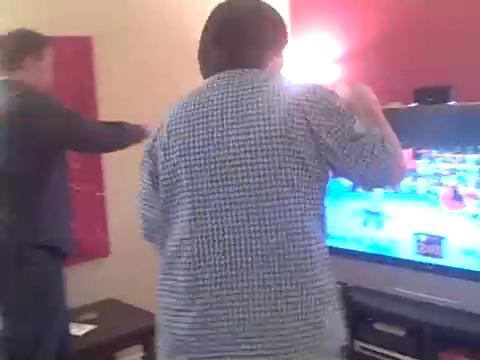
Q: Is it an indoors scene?
A: Yes, it is indoors.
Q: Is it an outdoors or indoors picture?
A: It is indoors.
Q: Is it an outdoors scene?
A: No, it is indoors.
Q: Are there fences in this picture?
A: No, there are no fences.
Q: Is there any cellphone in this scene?
A: No, there are no cell phones.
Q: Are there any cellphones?
A: No, there are no cellphones.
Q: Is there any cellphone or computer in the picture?
A: No, there are no cell phones or computers.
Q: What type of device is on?
A: The device is a screen.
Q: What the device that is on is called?
A: The device is a screen.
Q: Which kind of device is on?
A: The device is a screen.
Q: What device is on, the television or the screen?
A: The screen is on.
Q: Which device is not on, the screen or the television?
A: The television is not on.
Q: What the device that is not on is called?
A: The device is a television.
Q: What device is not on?
A: The device is a television.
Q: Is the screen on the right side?
A: Yes, the screen is on the right of the image.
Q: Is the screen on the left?
A: No, the screen is on the right of the image.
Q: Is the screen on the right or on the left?
A: The screen is on the right of the image.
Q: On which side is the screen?
A: The screen is on the right of the image.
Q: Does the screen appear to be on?
A: Yes, the screen is on.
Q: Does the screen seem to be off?
A: No, the screen is on.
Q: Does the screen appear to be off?
A: No, the screen is on.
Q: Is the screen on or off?
A: The screen is on.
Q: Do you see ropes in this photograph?
A: No, there are no ropes.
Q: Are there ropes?
A: No, there are no ropes.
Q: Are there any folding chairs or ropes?
A: No, there are no ropes or folding chairs.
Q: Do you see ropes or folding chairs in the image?
A: No, there are no ropes or folding chairs.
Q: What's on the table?
A: The paper is on the table.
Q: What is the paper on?
A: The paper is on the table.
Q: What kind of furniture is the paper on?
A: The paper is on the table.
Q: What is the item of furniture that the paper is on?
A: The piece of furniture is a table.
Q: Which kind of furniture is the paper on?
A: The paper is on the table.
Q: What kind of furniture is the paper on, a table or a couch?
A: The paper is on a table.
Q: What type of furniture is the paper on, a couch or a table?
A: The paper is on a table.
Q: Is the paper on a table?
A: Yes, the paper is on a table.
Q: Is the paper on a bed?
A: No, the paper is on a table.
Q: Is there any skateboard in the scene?
A: No, there are no skateboards.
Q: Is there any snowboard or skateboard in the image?
A: No, there are no skateboards or snowboards.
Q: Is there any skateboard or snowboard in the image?
A: No, there are no skateboards or snowboards.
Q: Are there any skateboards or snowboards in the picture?
A: No, there are no skateboards or snowboards.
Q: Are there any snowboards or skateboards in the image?
A: No, there are no skateboards or snowboards.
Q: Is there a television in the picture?
A: Yes, there is a television.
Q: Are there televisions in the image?
A: Yes, there is a television.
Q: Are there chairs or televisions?
A: Yes, there is a television.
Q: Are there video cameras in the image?
A: No, there are no video cameras.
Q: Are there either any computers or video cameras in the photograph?
A: No, there are no video cameras or computers.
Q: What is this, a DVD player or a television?
A: This is a television.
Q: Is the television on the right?
A: Yes, the television is on the right of the image.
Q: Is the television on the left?
A: No, the television is on the right of the image.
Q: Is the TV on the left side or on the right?
A: The TV is on the right of the image.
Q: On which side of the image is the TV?
A: The TV is on the right of the image.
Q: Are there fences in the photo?
A: No, there are no fences.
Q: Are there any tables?
A: Yes, there is a table.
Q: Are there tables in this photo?
A: Yes, there is a table.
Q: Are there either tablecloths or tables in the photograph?
A: Yes, there is a table.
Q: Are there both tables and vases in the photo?
A: No, there is a table but no vases.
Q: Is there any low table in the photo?
A: Yes, there is a low table.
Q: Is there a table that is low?
A: Yes, there is a table that is low.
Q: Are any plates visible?
A: No, there are no plates.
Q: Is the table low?
A: Yes, the table is low.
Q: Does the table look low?
A: Yes, the table is low.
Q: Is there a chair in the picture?
A: No, there are no chairs.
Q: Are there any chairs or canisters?
A: No, there are no chairs or canisters.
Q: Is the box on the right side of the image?
A: Yes, the box is on the right of the image.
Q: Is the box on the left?
A: No, the box is on the right of the image.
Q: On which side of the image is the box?
A: The box is on the right of the image.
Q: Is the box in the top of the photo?
A: No, the box is in the bottom of the image.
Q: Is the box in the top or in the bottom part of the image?
A: The box is in the bottom of the image.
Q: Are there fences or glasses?
A: No, there are no fences or glasses.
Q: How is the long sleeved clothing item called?
A: The clothing item is a shirt.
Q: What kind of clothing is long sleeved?
A: The clothing is a shirt.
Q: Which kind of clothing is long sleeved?
A: The clothing is a shirt.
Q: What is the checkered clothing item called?
A: The clothing item is a shirt.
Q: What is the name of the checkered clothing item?
A: The clothing item is a shirt.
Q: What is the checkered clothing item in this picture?
A: The clothing item is a shirt.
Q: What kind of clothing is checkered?
A: The clothing is a shirt.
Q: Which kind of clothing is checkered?
A: The clothing is a shirt.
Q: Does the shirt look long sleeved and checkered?
A: Yes, the shirt is long sleeved and checkered.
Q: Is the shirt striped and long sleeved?
A: No, the shirt is long sleeved but checkered.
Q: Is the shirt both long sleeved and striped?
A: No, the shirt is long sleeved but checkered.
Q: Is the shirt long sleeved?
A: Yes, the shirt is long sleeved.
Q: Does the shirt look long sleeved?
A: Yes, the shirt is long sleeved.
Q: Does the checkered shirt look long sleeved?
A: Yes, the shirt is long sleeved.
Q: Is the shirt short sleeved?
A: No, the shirt is long sleeved.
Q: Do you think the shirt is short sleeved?
A: No, the shirt is long sleeved.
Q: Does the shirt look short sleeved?
A: No, the shirt is long sleeved.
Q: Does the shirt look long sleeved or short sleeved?
A: The shirt is long sleeved.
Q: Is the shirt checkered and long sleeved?
A: Yes, the shirt is checkered and long sleeved.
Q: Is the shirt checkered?
A: Yes, the shirt is checkered.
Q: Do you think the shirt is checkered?
A: Yes, the shirt is checkered.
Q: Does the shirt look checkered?
A: Yes, the shirt is checkered.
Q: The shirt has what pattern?
A: The shirt is checkered.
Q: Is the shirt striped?
A: No, the shirt is checkered.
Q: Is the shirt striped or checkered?
A: The shirt is checkered.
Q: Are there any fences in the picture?
A: No, there are no fences.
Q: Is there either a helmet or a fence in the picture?
A: No, there are no fences or helmets.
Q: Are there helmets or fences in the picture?
A: No, there are no fences or helmets.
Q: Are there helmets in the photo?
A: No, there are no helmets.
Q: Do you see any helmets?
A: No, there are no helmets.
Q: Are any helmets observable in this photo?
A: No, there are no helmets.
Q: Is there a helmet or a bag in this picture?
A: No, there are no helmets or bags.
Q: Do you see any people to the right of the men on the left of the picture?
A: Yes, there is a person to the right of the men.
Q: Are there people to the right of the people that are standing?
A: Yes, there is a person to the right of the men.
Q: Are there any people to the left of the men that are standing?
A: No, the person is to the right of the men.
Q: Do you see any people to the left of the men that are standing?
A: No, the person is to the right of the men.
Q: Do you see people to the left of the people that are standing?
A: No, the person is to the right of the men.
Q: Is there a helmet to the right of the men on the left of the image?
A: No, there is a person to the right of the men.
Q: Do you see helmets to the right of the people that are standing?
A: No, there is a person to the right of the men.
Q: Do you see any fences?
A: No, there are no fences.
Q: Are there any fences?
A: No, there are no fences.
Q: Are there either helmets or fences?
A: No, there are no fences or helmets.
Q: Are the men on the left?
A: Yes, the men are on the left of the image.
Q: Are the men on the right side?
A: No, the men are on the left of the image.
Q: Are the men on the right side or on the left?
A: The men are on the left of the image.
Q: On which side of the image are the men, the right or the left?
A: The men are on the left of the image.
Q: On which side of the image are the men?
A: The men are on the left of the image.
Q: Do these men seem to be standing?
A: Yes, the men are standing.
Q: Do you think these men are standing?
A: Yes, the men are standing.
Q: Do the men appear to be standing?
A: Yes, the men are standing.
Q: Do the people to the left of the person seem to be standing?
A: Yes, the men are standing.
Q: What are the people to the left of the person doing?
A: The men are standing.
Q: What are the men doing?
A: The men are standing.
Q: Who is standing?
A: The men are standing.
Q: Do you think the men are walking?
A: No, the men are standing.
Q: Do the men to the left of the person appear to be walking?
A: No, the men are standing.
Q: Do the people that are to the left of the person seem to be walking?
A: No, the men are standing.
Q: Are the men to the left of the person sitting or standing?
A: The men are standing.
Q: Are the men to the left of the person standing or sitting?
A: The men are standing.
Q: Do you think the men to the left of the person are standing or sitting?
A: The men are standing.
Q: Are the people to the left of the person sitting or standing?
A: The men are standing.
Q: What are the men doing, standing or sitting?
A: The men are standing.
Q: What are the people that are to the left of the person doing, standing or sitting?
A: The men are standing.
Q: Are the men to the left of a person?
A: Yes, the men are to the left of a person.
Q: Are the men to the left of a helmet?
A: No, the men are to the left of a person.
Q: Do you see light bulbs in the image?
A: No, there are no light bulbs.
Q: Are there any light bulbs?
A: No, there are no light bulbs.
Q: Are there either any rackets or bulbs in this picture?
A: No, there are no bulbs or rackets.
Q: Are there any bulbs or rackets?
A: No, there are no bulbs or rackets.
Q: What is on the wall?
A: The artwork is on the wall.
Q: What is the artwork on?
A: The artwork is on the wall.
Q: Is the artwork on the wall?
A: Yes, the artwork is on the wall.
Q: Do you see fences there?
A: No, there are no fences.